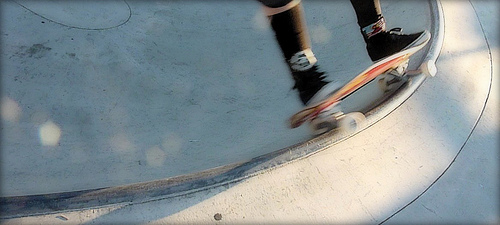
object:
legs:
[258, 0, 339, 106]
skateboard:
[287, 29, 432, 129]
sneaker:
[366, 28, 430, 62]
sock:
[266, 2, 316, 71]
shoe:
[289, 62, 346, 107]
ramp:
[0, 0, 446, 217]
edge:
[0, 44, 444, 212]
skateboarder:
[257, 0, 431, 129]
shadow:
[0, 139, 305, 223]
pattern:
[11, 0, 133, 30]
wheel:
[310, 115, 334, 134]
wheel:
[417, 58, 438, 77]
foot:
[293, 78, 341, 107]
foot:
[365, 30, 431, 63]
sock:
[352, 0, 384, 36]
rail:
[0, 125, 424, 218]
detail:
[289, 49, 317, 72]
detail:
[361, 17, 386, 39]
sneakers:
[291, 66, 348, 106]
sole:
[304, 79, 346, 107]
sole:
[408, 30, 432, 50]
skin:
[261, 0, 305, 18]